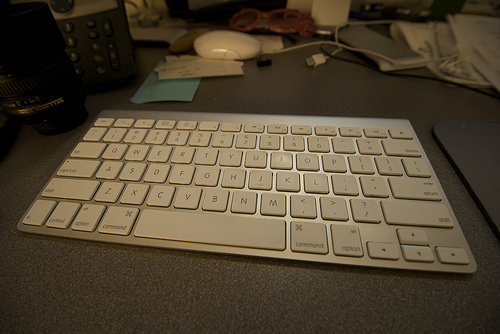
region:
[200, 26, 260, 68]
A white computer mouse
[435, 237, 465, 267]
A white keyboard button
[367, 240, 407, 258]
A white keyboard button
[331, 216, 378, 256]
A white keyboard button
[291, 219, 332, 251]
A white keyboard button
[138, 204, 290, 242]
A white keyboard button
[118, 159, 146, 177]
A white keyboard button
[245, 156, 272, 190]
A white keyboard button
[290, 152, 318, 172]
A white keyboard button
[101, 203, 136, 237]
A white keyboard button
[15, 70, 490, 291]
silver apple keyboard on desk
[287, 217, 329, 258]
command key of keyboard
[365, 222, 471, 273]
arrow keys on keyboard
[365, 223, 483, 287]
four arrow keys in corner of keyboard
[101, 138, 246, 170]
keys on qwerty keyboard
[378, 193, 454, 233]
shift key on right side of keyboard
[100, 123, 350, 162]
row of number keys on keyboard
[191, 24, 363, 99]
mouse and computer chords on desk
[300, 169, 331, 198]
l key on keyboard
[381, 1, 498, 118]
pile of papers on desk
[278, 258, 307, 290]
edge of a board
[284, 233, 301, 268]
pasr tof a button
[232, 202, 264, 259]
part of a button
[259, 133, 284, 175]
part of a board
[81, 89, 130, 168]
part of a board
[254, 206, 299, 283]
part of a button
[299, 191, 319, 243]
part of a button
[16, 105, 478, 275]
A keyboard on a desk.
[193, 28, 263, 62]
A mouse on a table.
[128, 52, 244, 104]
Papers on a desk.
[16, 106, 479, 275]
Keys on a keyboard.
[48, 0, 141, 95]
Part of a phone.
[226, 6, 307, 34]
Glasses on a desk.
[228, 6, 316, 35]
Glasses on a table.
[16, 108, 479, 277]
A keyboard on a table.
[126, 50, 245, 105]
Papers on a table.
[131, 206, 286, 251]
Space bar on keyboard.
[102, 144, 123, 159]
the key is white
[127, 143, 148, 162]
the key is white